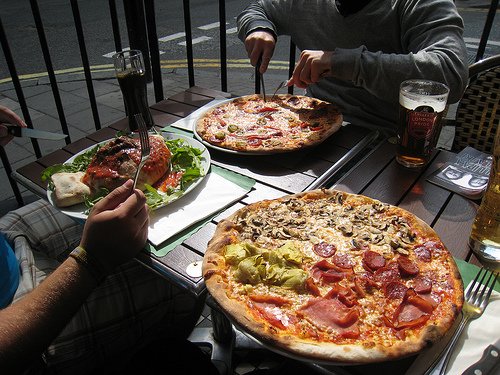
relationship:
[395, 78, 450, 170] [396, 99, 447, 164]
glass nearly full of beer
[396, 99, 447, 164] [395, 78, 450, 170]
beer in glass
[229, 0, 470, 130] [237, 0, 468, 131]
people wearing a jacket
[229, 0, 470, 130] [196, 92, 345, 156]
people cutting pizza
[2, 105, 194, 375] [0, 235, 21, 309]
person wearing a shirt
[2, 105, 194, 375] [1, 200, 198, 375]
person wearing shorts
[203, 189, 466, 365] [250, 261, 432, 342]
pizza has ham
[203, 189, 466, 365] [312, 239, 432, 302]
pizza has pepperoni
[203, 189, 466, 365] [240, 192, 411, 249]
pizza has mushrooms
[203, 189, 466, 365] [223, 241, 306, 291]
pizza has artichokes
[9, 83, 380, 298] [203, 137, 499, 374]
table beside table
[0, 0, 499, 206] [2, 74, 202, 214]
fence beside sidewalk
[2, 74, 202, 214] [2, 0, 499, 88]
sidewalk beside street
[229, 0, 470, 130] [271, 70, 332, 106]
people holding fork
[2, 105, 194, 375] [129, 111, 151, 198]
person holding fork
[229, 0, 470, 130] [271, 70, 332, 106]
people has a fork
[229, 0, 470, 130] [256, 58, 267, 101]
people has a knife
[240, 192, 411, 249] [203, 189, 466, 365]
mushrooms on pizza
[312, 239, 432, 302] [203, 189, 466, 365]
pepperoni on pizza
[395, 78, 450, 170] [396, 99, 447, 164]
glass full of beer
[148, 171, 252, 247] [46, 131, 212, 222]
napkin next to plate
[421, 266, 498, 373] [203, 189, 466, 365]
fork next to pizza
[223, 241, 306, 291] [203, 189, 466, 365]
artichokes on pizza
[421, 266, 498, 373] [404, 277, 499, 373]
fork on napkin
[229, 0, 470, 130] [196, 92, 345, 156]
people cutting into pizza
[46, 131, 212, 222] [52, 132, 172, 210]
plate with a meal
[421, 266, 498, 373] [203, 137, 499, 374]
fork on table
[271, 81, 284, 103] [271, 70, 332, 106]
tines on fork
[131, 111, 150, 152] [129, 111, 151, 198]
tines on fork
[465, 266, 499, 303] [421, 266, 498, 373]
tines on fork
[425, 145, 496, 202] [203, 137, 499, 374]
magazine on table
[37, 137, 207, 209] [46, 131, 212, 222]
lettuce on plate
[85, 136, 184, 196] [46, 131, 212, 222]
tomato sauce on plate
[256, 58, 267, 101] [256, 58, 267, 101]
knife has a knife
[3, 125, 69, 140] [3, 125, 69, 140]
knife has a knife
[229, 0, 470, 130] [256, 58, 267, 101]
people holding knife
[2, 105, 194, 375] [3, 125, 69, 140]
person holding knife